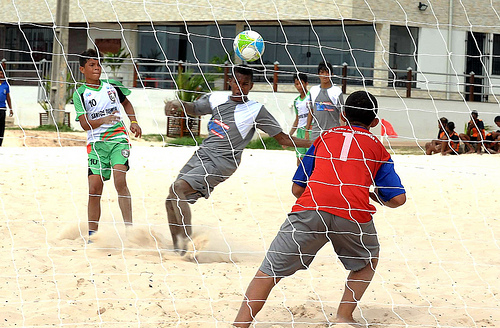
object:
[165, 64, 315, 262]
boy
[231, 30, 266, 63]
ball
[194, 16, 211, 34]
air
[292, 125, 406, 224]
shirt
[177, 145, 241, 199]
shorts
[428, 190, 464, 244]
sand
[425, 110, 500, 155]
children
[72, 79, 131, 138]
shirt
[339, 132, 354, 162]
number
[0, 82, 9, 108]
blue shirt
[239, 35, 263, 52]
colorful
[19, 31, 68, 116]
net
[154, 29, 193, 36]
rope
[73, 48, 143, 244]
boy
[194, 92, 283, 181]
shirt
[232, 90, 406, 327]
boy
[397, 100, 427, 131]
wall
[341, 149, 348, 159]
white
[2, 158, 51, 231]
beach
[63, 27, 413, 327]
game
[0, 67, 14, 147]
man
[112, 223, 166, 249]
dust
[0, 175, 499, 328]
ground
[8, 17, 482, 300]
photo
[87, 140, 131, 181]
green shorts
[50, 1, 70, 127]
post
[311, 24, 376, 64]
windows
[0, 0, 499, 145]
building